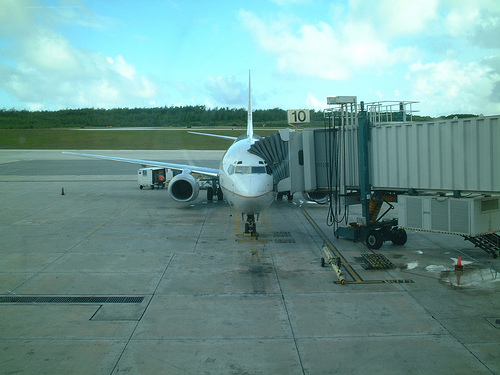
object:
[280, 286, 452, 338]
tile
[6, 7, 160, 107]
cloud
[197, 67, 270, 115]
cloud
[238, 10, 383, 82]
cloud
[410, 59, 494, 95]
cloud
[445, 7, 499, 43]
cloud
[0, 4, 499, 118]
sky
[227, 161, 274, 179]
window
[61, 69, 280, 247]
plane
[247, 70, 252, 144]
tail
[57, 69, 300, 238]
airplane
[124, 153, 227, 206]
van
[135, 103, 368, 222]
plane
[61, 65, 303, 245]
plane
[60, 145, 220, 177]
wing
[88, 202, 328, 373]
tile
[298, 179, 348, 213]
fuselage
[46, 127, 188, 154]
field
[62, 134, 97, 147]
green grass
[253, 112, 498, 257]
passenger unloader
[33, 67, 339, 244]
airplane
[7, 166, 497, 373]
tile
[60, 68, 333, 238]
airplane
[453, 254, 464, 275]
orange cone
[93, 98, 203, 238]
rectangular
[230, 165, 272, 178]
windows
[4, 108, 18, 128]
tree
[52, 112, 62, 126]
tree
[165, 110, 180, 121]
tree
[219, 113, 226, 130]
tree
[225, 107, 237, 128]
tree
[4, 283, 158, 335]
tile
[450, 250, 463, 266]
cone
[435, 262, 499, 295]
puddle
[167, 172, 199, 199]
engine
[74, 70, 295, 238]
airplane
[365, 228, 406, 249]
two wheels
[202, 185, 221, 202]
two wheels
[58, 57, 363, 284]
airplane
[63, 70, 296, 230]
plane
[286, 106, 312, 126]
sign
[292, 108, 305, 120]
10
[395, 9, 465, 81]
clouds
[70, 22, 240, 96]
sky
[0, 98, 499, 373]
airport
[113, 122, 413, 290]
aircraft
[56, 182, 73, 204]
striped sheet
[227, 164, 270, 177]
windshield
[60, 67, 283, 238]
airplane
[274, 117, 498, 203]
walkway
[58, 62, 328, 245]
plane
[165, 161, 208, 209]
engine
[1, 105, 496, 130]
trees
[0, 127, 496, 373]
airport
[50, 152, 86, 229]
cone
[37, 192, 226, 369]
concrete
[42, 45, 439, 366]
airport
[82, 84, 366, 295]
plane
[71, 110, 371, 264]
plane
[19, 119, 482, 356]
ground